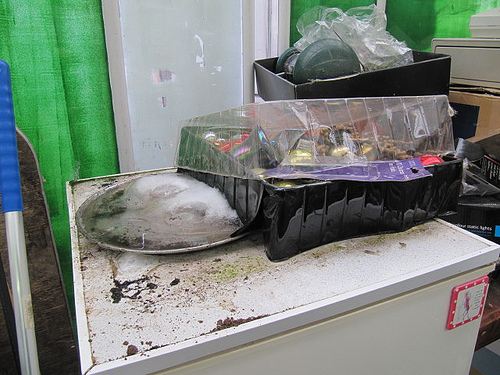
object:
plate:
[73, 228, 151, 290]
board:
[75, 177, 493, 363]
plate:
[125, 65, 160, 81]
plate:
[291, 38, 361, 82]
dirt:
[111, 279, 158, 304]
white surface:
[63, 160, 500, 375]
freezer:
[63, 169, 499, 375]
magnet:
[446, 276, 489, 332]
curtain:
[0, 0, 128, 334]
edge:
[446, 287, 459, 330]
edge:
[453, 276, 489, 291]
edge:
[447, 313, 483, 331]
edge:
[479, 276, 491, 318]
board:
[446, 275, 489, 332]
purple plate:
[263, 159, 430, 181]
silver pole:
[3, 211, 41, 375]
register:
[429, 7, 498, 89]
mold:
[76, 172, 252, 254]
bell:
[230, 125, 277, 168]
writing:
[475, 286, 484, 312]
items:
[195, 121, 446, 188]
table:
[63, 165, 498, 375]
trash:
[195, 113, 449, 189]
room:
[0, 0, 500, 374]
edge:
[344, 255, 477, 314]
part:
[77, 329, 91, 371]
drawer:
[73, 266, 488, 375]